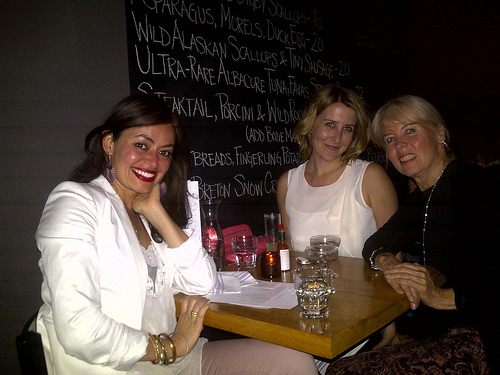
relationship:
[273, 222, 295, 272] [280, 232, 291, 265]
sauce in a bottle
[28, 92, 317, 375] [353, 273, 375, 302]
woman sitting at table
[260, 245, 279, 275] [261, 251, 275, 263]
candle with a flame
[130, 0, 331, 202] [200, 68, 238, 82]
menu written with chalk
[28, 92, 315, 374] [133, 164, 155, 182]
woman wearing lipstick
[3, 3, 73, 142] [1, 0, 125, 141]
section of gray wall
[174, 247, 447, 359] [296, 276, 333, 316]
table with glass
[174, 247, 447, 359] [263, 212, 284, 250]
table with glass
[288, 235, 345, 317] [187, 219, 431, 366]
glasses on table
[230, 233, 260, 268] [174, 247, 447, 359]
glasses on table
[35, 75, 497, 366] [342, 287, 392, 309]
woman sitting at table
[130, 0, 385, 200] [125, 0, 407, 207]
chalk on blackboard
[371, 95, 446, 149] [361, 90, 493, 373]
hair on woman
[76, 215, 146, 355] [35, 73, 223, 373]
jacket on woman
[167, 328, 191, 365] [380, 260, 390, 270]
bracelet on wrist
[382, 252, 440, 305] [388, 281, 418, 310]
hand on top of hand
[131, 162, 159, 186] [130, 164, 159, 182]
lips and teeth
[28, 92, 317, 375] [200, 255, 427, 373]
woman sitting at table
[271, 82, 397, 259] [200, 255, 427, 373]
woman sitting at table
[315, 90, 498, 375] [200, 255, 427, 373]
woman sitting at table